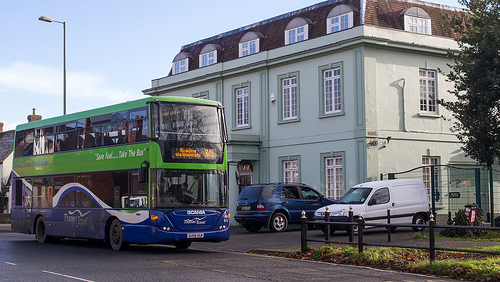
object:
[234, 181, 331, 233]
vehicle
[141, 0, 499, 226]
building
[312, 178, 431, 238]
van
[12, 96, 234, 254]
bus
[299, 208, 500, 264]
fence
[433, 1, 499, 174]
tree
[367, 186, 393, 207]
window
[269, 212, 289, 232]
tire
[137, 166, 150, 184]
mirror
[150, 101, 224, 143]
window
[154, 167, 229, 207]
window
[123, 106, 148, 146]
window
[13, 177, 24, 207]
window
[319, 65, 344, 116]
window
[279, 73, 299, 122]
window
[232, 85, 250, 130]
window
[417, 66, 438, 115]
window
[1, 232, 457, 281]
street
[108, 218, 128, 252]
tire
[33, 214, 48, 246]
tire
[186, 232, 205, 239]
tag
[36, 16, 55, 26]
street light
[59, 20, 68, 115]
post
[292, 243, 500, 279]
grass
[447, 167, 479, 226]
door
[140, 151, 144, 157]
letters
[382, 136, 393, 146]
camera